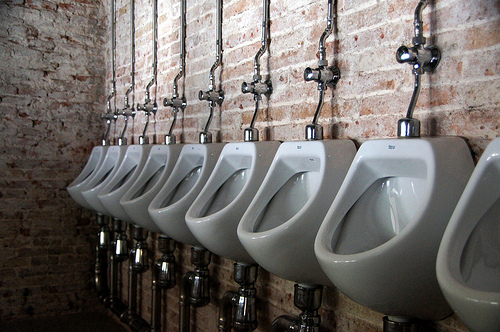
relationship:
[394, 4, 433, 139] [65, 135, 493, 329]
pipe attached to urinals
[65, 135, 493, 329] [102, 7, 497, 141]
urinals against wall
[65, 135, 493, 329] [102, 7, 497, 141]
urinals attached to wall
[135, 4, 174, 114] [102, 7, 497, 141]
sunlight on wall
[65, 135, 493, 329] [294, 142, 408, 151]
urinals have printing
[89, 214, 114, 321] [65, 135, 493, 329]
pipe below urinals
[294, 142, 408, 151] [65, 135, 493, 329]
printing on urinals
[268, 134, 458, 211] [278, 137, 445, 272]
sunlight shining on urnials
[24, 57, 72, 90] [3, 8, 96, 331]
crack in wall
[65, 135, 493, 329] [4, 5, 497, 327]
urinals in bathroom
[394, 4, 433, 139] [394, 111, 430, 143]
pipe attached to urnial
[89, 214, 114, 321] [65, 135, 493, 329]
pipe under urinals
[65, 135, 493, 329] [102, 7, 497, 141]
urinals on wall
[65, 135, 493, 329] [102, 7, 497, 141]
urinals attached to a brick wall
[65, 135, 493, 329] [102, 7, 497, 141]
urinals attached to a wall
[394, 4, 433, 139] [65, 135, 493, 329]
pipe above urinals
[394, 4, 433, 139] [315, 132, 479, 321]
pipe attached to urinal